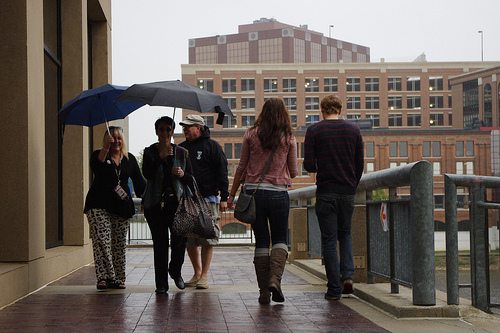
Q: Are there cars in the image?
A: No, there are no cars.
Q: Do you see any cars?
A: No, there are no cars.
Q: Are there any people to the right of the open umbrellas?
A: Yes, there is a person to the right of the umbrellas.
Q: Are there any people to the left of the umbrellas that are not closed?
A: No, the person is to the right of the umbrellas.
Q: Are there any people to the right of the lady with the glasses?
A: Yes, there is a person to the right of the lady.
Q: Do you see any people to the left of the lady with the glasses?
A: No, the person is to the right of the lady.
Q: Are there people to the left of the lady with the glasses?
A: No, the person is to the right of the lady.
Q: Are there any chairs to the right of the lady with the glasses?
A: No, there is a person to the right of the lady.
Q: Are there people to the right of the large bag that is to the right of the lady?
A: Yes, there is a person to the right of the bag.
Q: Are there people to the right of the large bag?
A: Yes, there is a person to the right of the bag.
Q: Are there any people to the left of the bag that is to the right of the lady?
A: No, the person is to the right of the bag.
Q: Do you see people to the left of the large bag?
A: No, the person is to the right of the bag.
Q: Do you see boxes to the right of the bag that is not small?
A: No, there is a person to the right of the bag.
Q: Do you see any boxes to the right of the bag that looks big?
A: No, there is a person to the right of the bag.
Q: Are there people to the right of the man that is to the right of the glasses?
A: Yes, there is a person to the right of the man.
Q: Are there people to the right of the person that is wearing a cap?
A: Yes, there is a person to the right of the man.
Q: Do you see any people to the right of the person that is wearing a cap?
A: Yes, there is a person to the right of the man.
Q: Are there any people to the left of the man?
A: No, the person is to the right of the man.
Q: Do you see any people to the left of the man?
A: No, the person is to the right of the man.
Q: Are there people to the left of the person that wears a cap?
A: No, the person is to the right of the man.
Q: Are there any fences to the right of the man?
A: No, there is a person to the right of the man.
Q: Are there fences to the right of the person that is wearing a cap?
A: No, there is a person to the right of the man.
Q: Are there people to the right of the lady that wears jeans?
A: Yes, there is a person to the right of the lady.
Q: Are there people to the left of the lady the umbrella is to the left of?
A: No, the person is to the right of the lady.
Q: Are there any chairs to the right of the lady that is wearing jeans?
A: No, there is a person to the right of the lady.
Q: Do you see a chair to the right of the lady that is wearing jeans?
A: No, there is a person to the right of the lady.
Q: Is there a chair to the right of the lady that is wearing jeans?
A: No, there is a person to the right of the lady.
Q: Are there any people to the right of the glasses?
A: Yes, there is a person to the right of the glasses.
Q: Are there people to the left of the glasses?
A: No, the person is to the right of the glasses.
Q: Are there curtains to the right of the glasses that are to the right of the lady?
A: No, there is a person to the right of the glasses.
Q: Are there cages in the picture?
A: No, there are no cages.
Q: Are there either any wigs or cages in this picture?
A: No, there are no cages or wigs.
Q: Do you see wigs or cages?
A: No, there are no cages or wigs.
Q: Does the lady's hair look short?
A: Yes, the hair is short.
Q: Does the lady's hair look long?
A: No, the hair is short.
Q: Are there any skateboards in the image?
A: No, there are no skateboards.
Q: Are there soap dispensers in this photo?
A: No, there are no soap dispensers.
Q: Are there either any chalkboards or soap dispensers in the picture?
A: No, there are no soap dispensers or chalkboards.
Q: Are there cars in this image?
A: No, there are no cars.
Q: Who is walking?
A: The people are walking.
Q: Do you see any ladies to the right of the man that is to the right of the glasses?
A: Yes, there is a lady to the right of the man.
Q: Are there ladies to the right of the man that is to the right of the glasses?
A: Yes, there is a lady to the right of the man.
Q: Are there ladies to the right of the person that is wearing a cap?
A: Yes, there is a lady to the right of the man.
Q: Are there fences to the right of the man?
A: No, there is a lady to the right of the man.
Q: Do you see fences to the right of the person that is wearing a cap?
A: No, there is a lady to the right of the man.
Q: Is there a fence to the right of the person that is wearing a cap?
A: No, there is a lady to the right of the man.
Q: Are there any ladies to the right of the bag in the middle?
A: Yes, there is a lady to the right of the bag.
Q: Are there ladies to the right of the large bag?
A: Yes, there is a lady to the right of the bag.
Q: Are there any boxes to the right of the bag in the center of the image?
A: No, there is a lady to the right of the bag.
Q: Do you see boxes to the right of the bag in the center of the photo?
A: No, there is a lady to the right of the bag.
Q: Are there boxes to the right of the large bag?
A: No, there is a lady to the right of the bag.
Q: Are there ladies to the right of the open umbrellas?
A: Yes, there is a lady to the right of the umbrellas.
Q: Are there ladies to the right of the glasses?
A: Yes, there is a lady to the right of the glasses.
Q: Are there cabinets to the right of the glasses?
A: No, there is a lady to the right of the glasses.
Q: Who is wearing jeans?
A: The lady is wearing jeans.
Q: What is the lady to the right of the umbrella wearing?
A: The lady is wearing jeans.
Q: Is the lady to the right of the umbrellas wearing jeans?
A: Yes, the lady is wearing jeans.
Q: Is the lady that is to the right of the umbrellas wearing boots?
A: No, the lady is wearing jeans.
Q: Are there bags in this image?
A: Yes, there is a bag.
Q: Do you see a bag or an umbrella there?
A: Yes, there is a bag.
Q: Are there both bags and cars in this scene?
A: No, there is a bag but no cars.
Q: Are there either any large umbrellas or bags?
A: Yes, there is a large bag.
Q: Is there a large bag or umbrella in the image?
A: Yes, there is a large bag.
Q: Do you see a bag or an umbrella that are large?
A: Yes, the bag is large.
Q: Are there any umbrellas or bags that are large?
A: Yes, the bag is large.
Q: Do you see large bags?
A: Yes, there is a large bag.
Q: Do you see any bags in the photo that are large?
A: Yes, there is a bag that is large.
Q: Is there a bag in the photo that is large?
A: Yes, there is a bag that is large.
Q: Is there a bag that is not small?
A: Yes, there is a large bag.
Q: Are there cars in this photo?
A: No, there are no cars.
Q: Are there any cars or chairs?
A: No, there are no cars or chairs.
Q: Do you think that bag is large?
A: Yes, the bag is large.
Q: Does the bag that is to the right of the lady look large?
A: Yes, the bag is large.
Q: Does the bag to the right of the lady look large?
A: Yes, the bag is large.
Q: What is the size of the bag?
A: The bag is large.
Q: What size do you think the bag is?
A: The bag is large.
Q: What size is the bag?
A: The bag is large.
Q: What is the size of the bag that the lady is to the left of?
A: The bag is large.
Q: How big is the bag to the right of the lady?
A: The bag is large.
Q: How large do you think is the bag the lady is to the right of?
A: The bag is large.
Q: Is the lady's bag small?
A: No, the bag is large.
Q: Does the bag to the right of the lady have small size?
A: No, the bag is large.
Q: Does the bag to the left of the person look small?
A: No, the bag is large.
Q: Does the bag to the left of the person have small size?
A: No, the bag is large.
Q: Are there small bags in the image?
A: No, there is a bag but it is large.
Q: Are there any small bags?
A: No, there is a bag but it is large.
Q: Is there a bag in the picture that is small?
A: No, there is a bag but it is large.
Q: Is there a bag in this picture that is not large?
A: No, there is a bag but it is large.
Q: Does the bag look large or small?
A: The bag is large.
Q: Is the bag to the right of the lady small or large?
A: The bag is large.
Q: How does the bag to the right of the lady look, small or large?
A: The bag is large.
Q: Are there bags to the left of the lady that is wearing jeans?
A: Yes, there is a bag to the left of the lady.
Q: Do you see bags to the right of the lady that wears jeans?
A: No, the bag is to the left of the lady.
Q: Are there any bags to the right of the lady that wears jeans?
A: No, the bag is to the left of the lady.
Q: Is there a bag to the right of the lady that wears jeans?
A: No, the bag is to the left of the lady.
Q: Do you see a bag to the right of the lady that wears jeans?
A: No, the bag is to the left of the lady.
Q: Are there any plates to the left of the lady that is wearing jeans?
A: No, there is a bag to the left of the lady.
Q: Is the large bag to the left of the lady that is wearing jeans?
A: Yes, the bag is to the left of the lady.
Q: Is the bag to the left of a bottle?
A: No, the bag is to the left of the lady.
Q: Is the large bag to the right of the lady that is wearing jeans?
A: No, the bag is to the left of the lady.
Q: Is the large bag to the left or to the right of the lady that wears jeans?
A: The bag is to the left of the lady.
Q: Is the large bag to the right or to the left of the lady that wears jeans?
A: The bag is to the left of the lady.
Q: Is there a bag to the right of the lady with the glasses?
A: Yes, there is a bag to the right of the lady.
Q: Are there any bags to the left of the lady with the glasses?
A: No, the bag is to the right of the lady.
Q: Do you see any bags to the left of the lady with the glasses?
A: No, the bag is to the right of the lady.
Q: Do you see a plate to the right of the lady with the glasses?
A: No, there is a bag to the right of the lady.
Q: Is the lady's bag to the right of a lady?
A: Yes, the bag is to the right of a lady.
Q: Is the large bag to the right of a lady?
A: Yes, the bag is to the right of a lady.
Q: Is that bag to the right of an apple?
A: No, the bag is to the right of a lady.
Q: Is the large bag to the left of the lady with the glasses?
A: No, the bag is to the right of the lady.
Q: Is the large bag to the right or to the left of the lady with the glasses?
A: The bag is to the right of the lady.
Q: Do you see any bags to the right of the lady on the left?
A: Yes, there is a bag to the right of the lady.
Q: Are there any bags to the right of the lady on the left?
A: Yes, there is a bag to the right of the lady.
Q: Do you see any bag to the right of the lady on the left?
A: Yes, there is a bag to the right of the lady.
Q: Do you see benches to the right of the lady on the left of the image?
A: No, there is a bag to the right of the lady.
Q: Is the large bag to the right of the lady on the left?
A: Yes, the bag is to the right of the lady.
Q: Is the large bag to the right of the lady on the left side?
A: Yes, the bag is to the right of the lady.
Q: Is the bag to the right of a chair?
A: No, the bag is to the right of the lady.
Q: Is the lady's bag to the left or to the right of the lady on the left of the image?
A: The bag is to the right of the lady.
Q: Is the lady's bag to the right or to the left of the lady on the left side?
A: The bag is to the right of the lady.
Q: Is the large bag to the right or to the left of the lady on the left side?
A: The bag is to the right of the lady.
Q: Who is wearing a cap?
A: The man is wearing a cap.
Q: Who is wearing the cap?
A: The man is wearing a cap.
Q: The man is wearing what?
A: The man is wearing a cap.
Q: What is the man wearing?
A: The man is wearing a cap.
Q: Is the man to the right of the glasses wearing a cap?
A: Yes, the man is wearing a cap.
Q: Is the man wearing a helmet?
A: No, the man is wearing a cap.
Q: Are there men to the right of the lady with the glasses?
A: Yes, there is a man to the right of the lady.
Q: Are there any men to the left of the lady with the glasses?
A: No, the man is to the right of the lady.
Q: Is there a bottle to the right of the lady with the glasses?
A: No, there is a man to the right of the lady.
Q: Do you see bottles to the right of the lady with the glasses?
A: No, there is a man to the right of the lady.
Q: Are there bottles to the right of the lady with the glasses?
A: No, there is a man to the right of the lady.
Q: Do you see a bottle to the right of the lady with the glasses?
A: No, there is a man to the right of the lady.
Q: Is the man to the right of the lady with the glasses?
A: Yes, the man is to the right of the lady.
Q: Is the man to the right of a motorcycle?
A: No, the man is to the right of the lady.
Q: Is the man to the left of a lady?
A: No, the man is to the right of a lady.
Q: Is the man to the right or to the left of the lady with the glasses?
A: The man is to the right of the lady.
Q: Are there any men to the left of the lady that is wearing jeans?
A: Yes, there is a man to the left of the lady.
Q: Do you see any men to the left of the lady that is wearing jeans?
A: Yes, there is a man to the left of the lady.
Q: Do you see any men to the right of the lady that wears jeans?
A: No, the man is to the left of the lady.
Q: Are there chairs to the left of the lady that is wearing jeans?
A: No, there is a man to the left of the lady.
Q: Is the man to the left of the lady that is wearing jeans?
A: Yes, the man is to the left of the lady.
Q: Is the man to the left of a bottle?
A: No, the man is to the left of the lady.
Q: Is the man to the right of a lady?
A: No, the man is to the left of a lady.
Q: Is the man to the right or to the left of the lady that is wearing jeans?
A: The man is to the left of the lady.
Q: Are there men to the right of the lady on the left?
A: Yes, there is a man to the right of the lady.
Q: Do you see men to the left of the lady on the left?
A: No, the man is to the right of the lady.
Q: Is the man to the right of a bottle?
A: No, the man is to the right of a lady.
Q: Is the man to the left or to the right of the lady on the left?
A: The man is to the right of the lady.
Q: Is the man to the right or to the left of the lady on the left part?
A: The man is to the right of the lady.